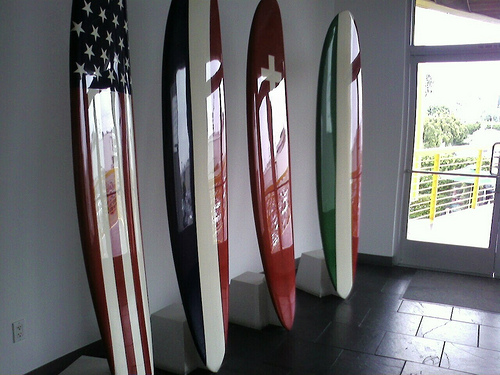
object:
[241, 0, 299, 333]
surf boards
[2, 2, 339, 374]
wall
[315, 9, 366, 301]
graphic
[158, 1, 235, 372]
surfboard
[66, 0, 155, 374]
american flag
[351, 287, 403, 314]
tile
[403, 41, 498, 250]
glass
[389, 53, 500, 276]
door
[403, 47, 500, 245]
glass door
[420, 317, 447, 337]
crack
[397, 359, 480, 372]
tiles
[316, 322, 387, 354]
tile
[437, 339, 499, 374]
tile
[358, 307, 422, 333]
tile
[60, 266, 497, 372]
floor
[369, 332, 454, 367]
grey tile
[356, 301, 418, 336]
tile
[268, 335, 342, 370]
tile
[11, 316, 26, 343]
electrical outlet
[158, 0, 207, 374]
blue surfboard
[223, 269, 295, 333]
box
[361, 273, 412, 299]
tile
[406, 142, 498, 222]
guard rail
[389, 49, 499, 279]
doorway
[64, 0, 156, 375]
surf board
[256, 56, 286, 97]
cross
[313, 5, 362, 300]
surfboard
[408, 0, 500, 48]
window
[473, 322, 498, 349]
tile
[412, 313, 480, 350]
tile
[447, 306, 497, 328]
tile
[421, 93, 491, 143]
trees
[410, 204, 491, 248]
cement surface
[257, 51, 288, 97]
cross design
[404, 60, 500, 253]
outdoors